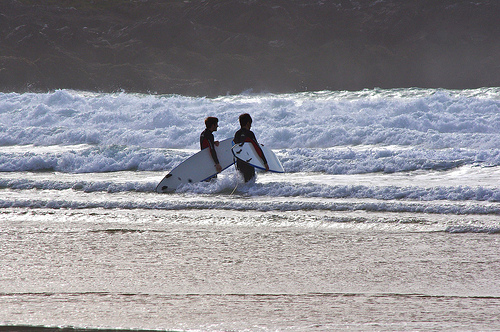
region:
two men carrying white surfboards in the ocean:
[159, 102, 291, 194]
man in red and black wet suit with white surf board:
[151, 112, 243, 202]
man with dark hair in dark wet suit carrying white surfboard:
[231, 107, 287, 197]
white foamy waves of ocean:
[10, 80, 499, 223]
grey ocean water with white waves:
[0, 1, 499, 326]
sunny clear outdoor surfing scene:
[8, 5, 498, 325]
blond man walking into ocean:
[153, 112, 229, 199]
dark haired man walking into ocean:
[229, 110, 289, 196]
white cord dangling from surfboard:
[225, 158, 242, 204]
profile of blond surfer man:
[196, 115, 231, 197]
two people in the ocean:
[198, 99, 266, 194]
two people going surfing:
[191, 110, 271, 196]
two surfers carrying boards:
[194, 100, 273, 197]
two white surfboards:
[148, 131, 285, 197]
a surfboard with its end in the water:
[151, 126, 242, 206]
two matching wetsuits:
[196, 125, 270, 188]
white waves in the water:
[3, 78, 498, 204]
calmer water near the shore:
[1, 208, 498, 329]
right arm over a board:
[245, 131, 272, 173]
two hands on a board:
[211, 135, 227, 177]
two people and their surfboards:
[154, 113, 282, 193]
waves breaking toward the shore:
[2, 84, 497, 229]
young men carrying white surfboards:
[156, 110, 283, 193]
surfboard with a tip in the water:
[156, 132, 235, 190]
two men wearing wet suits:
[200, 115, 270, 185]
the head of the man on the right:
[238, 113, 253, 129]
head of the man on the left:
[204, 114, 221, 131]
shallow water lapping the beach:
[0, 295, 499, 330]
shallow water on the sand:
[0, 294, 499, 329]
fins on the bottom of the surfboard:
[235, 138, 251, 164]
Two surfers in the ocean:
[159, 113, 284, 195]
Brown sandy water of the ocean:
[96, 242, 378, 315]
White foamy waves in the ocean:
[271, 88, 466, 148]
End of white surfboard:
[159, 163, 214, 197]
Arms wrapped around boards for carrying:
[196, 142, 278, 180]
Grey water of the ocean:
[79, 17, 322, 72]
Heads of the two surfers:
[197, 112, 257, 134]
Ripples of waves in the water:
[7, 146, 87, 213]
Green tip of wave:
[370, 85, 429, 92]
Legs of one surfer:
[234, 163, 262, 192]